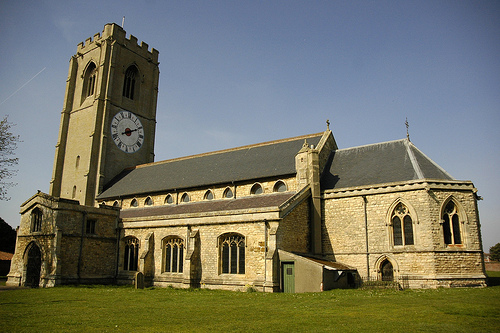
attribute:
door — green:
[275, 260, 303, 297]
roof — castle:
[75, 24, 162, 59]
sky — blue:
[9, 4, 481, 155]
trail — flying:
[5, 53, 56, 100]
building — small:
[0, 233, 23, 287]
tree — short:
[487, 238, 499, 262]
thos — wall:
[336, 197, 384, 257]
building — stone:
[11, 17, 490, 290]